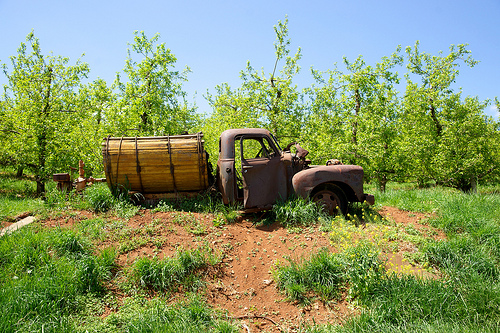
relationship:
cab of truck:
[295, 156, 375, 209] [101, 131, 390, 220]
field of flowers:
[0, 2, 500, 333] [325, 210, 427, 272]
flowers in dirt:
[321, 220, 405, 250] [154, 221, 315, 267]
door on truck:
[218, 121, 289, 213] [103, 134, 363, 214]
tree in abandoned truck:
[403, 37, 485, 179] [101, 128, 374, 219]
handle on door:
[244, 161, 254, 181] [240, 134, 293, 221]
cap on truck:
[224, 169, 232, 175] [96, 123, 379, 219]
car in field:
[94, 135, 381, 216] [4, 2, 469, 321]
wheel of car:
[310, 178, 355, 218] [96, 135, 414, 238]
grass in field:
[22, 222, 471, 327] [10, 35, 485, 331]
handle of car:
[243, 164, 253, 171] [92, 130, 372, 215]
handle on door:
[243, 164, 253, 171] [238, 140, 273, 209]